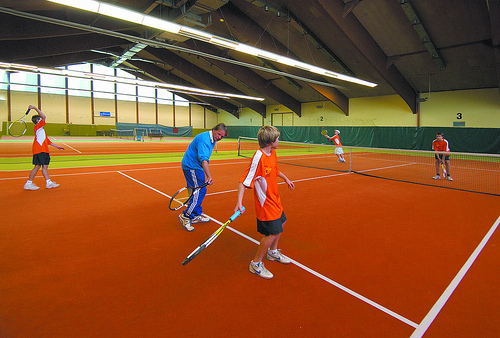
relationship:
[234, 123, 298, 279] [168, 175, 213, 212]
boy with tennis racket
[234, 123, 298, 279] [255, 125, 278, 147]
boy has hair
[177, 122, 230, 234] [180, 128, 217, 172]
man wearing blue shirt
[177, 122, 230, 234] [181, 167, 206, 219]
man wearing pants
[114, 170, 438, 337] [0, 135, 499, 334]
white line in ground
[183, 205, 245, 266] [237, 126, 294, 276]
bat by boy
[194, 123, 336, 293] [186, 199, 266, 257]
boy holding bat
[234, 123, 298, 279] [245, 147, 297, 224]
boy wearing shirt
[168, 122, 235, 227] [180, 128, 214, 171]
man wearing blue shirt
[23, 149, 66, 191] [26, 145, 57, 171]
girl wearing shorts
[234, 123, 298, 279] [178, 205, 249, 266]
boy holds bat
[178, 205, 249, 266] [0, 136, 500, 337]
bat on ground